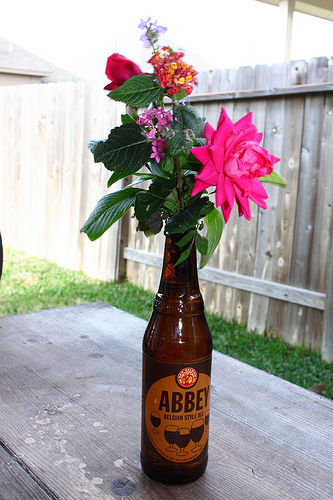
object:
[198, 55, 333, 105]
plank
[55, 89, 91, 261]
plank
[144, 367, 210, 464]
label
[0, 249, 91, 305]
green lawn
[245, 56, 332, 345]
plank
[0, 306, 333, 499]
wooden table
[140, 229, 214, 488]
vase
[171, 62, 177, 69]
yellow flower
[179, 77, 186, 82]
yellow flower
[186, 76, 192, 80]
yellow flower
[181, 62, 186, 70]
yellow flower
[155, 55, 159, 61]
yellow flower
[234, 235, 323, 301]
fence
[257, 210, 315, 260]
wooden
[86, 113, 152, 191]
leaf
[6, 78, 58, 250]
plank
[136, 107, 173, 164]
flower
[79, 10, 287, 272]
flower cluster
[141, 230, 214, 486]
beer bottle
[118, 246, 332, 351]
plank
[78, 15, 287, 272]
cluster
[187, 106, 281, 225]
flower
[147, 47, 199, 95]
flower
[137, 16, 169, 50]
flower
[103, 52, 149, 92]
flower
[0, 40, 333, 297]
wall